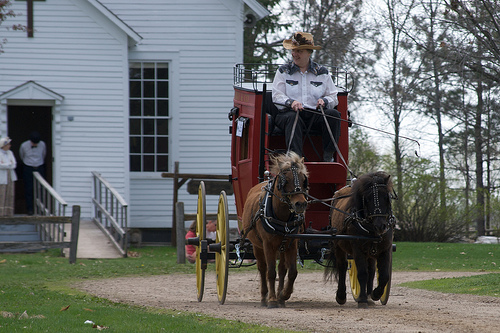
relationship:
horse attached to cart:
[330, 172, 400, 306] [155, 62, 395, 312]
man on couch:
[270, 27, 343, 164] [171, 62, 416, 317]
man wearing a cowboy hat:
[270, 27, 343, 164] [279, 30, 325, 50]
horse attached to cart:
[217, 158, 316, 288] [219, 48, 350, 195]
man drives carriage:
[265, 27, 347, 164] [185, 59, 417, 319]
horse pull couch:
[240, 150, 312, 308] [171, 62, 416, 317]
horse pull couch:
[323, 171, 400, 311] [171, 62, 416, 317]